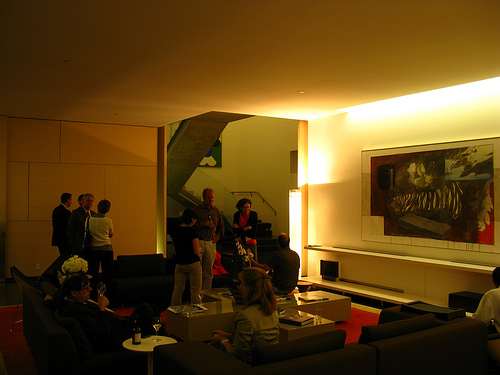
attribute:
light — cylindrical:
[282, 186, 306, 277]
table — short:
[160, 285, 352, 347]